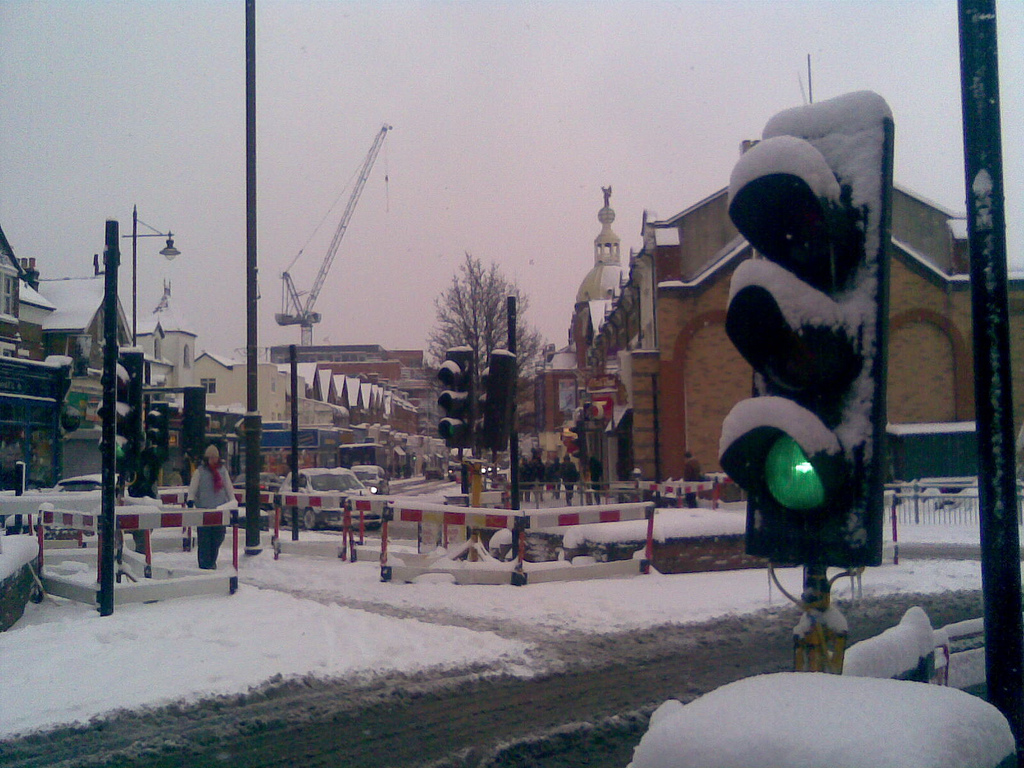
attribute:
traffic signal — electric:
[695, 96, 907, 596]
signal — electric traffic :
[697, 89, 898, 561]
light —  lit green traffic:
[754, 439, 826, 517]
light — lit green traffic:
[745, 444, 830, 527]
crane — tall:
[265, 103, 421, 365]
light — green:
[765, 434, 832, 510]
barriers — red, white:
[1, 482, 650, 606]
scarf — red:
[199, 459, 234, 494]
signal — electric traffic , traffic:
[712, 89, 896, 584]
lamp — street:
[134, 219, 184, 265]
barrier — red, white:
[104, 500, 245, 613]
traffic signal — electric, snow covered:
[415, 337, 487, 444]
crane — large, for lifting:
[267, 107, 412, 354]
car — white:
[280, 462, 391, 538]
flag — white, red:
[583, 386, 612, 428]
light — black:
[715, 89, 890, 558]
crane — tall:
[284, 117, 397, 347]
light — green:
[768, 426, 833, 515]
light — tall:
[122, 209, 187, 344]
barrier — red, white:
[378, 497, 659, 590]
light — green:
[758, 426, 828, 517]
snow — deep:
[23, 544, 993, 763]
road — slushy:
[4, 577, 977, 761]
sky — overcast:
[6, 0, 1020, 368]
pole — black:
[90, 214, 127, 599]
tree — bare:
[436, 246, 562, 424]